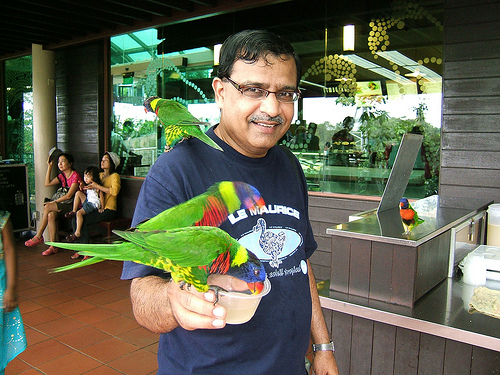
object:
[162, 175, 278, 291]
birds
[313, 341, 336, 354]
watch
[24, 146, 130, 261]
family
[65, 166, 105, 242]
child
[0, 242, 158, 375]
floor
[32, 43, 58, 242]
pole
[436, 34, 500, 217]
siding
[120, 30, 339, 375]
man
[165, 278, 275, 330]
hand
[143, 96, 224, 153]
bird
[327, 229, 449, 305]
wood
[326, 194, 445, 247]
counter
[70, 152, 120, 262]
woman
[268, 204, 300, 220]
lettering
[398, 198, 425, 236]
bird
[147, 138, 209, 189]
shoulder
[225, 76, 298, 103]
glasses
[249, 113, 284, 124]
mustache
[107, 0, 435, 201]
window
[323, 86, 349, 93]
logo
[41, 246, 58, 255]
sandals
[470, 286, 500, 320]
tray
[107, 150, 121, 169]
hat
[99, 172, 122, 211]
shirt